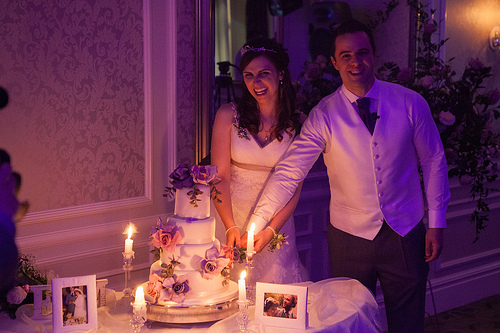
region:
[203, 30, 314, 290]
smiling dark haired bride with tiara on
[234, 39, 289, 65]
silver tiara on head of dark hair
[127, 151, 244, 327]
four tiered wedding cake with frosting decorative roses on sides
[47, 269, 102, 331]
picture of bride and groom in white frame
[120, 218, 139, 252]
lit white candle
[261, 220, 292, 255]
corsage with yellow flower and white wrist band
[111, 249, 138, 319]
clear glass candle stick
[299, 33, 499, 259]
huge rose boquet with greenery on wall with groom standing in front of it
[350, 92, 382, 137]
man's black tie tucked into white vest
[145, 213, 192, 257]
decorative rose made of frosting on side of cake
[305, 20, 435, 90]
the head of a man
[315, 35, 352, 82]
the ear of a man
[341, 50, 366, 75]
the nose of a man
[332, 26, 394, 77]
the eyes of a man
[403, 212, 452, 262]
the hand of a man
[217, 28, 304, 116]
the head of a woman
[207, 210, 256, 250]
the hand of a woman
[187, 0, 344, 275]
a woman wearing a dress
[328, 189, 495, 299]
a man wearing pants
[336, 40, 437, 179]
a man wearing a tie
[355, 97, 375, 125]
a man's tie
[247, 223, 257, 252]
a white lit candle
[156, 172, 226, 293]
a small four tier cake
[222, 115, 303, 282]
part of a woman's white wedding dress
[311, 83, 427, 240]
a man's white vest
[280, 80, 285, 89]
a woman's earring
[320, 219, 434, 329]
part of a man's pants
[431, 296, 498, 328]
part of a carpet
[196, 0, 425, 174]
part of a large wall mirror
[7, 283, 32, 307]
a rose flower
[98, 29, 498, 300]
a newly married couple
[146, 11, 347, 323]
a couple cutting the cake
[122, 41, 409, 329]
a couple cutting ona wedding cake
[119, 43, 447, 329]
a woman wearing a wedding dress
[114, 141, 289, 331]
a wedding cake on a table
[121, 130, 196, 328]
a teired wedding cake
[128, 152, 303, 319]
a tiered cake on the table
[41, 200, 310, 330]
pictures on a table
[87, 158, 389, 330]
candles on a table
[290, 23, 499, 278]
a man in a suit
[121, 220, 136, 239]
Yellow flame on top of candle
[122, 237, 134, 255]
Long white tapered candle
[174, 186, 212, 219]
Top tier on wedding cake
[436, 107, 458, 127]
Pink rose on plant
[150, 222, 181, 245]
Pink rose on wedding cake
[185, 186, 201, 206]
Green leaves on wedding cake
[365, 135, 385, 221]
Buttons in a line on vest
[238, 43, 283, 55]
Floral headband in hair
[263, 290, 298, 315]
Picture of man and woman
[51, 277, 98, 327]
Solid white picture frame